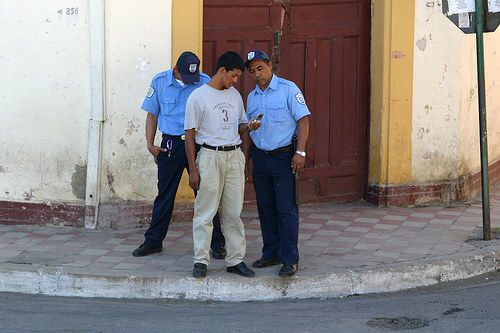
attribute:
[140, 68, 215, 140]
shirt — blue 